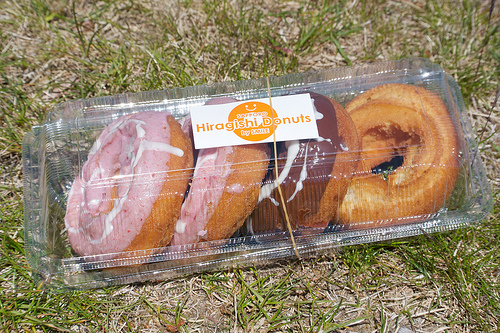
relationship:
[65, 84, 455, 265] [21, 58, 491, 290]
donuts in case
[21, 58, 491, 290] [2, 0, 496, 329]
case on grass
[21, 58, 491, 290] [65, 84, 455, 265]
case has donuts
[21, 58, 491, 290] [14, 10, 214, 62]
case on ground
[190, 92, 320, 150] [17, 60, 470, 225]
label on lid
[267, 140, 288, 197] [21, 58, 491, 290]
band around case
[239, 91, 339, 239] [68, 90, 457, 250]
frosting on donuts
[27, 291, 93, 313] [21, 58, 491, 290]
grass next to case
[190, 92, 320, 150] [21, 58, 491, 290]
label on case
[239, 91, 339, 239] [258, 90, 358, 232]
frosting on donut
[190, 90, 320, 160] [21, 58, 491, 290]
label on case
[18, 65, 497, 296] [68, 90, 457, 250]
case on donuts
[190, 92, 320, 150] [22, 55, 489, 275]
label on case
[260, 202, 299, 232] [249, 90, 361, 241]
frosting on donut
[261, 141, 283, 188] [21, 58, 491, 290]
band on case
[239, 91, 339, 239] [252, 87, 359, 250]
frosting on donuts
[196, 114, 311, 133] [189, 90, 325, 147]
letters on sticker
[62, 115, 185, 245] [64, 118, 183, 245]
frosting drizzled over frosting